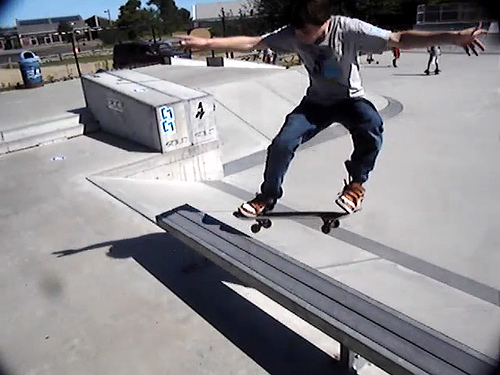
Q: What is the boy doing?
A: Skateboarding.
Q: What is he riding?
A: A skateboard.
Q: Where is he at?
A: A skatepark.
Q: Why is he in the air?
A: He is doing a trick.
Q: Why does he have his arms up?
A: For balance.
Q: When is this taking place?
A: Mid afternoon.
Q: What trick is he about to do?
A: Grind on a bench.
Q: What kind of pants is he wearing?
A: Blue jeans.